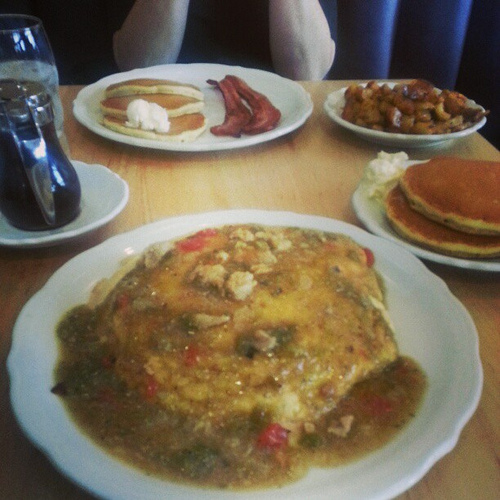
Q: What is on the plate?
A: Food.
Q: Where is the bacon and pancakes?
A: On the plate.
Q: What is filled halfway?
A: The drink.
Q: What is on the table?
A: Bowl of food.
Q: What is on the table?
A: A plate of pancakes.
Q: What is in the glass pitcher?
A: Syrup.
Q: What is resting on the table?
A: Person's arm.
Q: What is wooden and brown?
A: A table.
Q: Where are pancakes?
A: On plate.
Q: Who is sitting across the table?
A: A person.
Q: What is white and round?
A: Plates.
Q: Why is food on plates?
A: To be eaten.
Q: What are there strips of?
A: Bacon.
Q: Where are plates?
A: On the table.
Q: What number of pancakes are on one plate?
A: Three.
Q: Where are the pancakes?
A: On plates.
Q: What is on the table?
A: Food.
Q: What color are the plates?
A: White.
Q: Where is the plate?
A: On a table.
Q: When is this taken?
A: During a meal.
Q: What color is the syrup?
A: Brown.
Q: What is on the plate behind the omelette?
A: Bacon.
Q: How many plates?
A: Five.